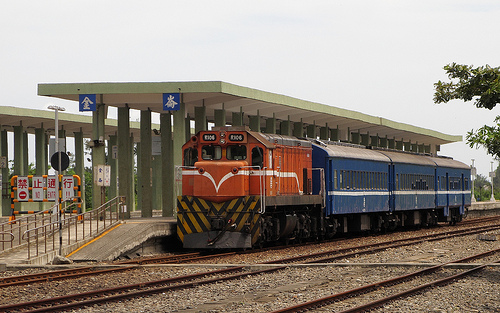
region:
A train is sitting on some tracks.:
[172, 125, 473, 256]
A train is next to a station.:
[175, 125, 473, 252]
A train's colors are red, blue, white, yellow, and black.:
[173, 127, 470, 250]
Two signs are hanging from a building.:
[75, 88, 185, 113]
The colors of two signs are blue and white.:
[77, 90, 179, 111]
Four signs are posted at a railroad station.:
[16, 173, 74, 201]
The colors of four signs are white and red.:
[16, 175, 74, 201]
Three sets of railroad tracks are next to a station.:
[0, 204, 498, 311]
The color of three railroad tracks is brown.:
[0, 210, 498, 312]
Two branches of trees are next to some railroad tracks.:
[430, 61, 498, 205]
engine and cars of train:
[164, 123, 480, 256]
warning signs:
[10, 171, 95, 222]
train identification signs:
[67, 90, 185, 117]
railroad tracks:
[2, 206, 496, 311]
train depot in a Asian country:
[30, 76, 484, 248]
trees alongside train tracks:
[409, 43, 494, 272]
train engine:
[164, 124, 320, 261]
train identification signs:
[195, 125, 250, 143]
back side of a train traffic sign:
[45, 145, 86, 270]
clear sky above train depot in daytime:
[0, 208, 498, 218]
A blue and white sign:
[156, 86, 186, 119]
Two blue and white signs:
[76, 89, 186, 116]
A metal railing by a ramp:
[25, 216, 72, 266]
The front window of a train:
[197, 141, 249, 163]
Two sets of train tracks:
[138, 252, 441, 311]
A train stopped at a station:
[167, 120, 476, 256]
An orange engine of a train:
[170, 122, 325, 255]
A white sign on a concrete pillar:
[90, 161, 117, 194]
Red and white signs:
[10, 170, 82, 209]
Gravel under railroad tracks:
[159, 255, 461, 293]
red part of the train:
[175, 125, 317, 200]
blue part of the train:
[306, 138, 476, 216]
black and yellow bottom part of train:
[171, 193, 265, 250]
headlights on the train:
[196, 163, 241, 175]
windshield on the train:
[197, 142, 250, 166]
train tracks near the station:
[1, 211, 498, 311]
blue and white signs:
[78, 93, 181, 117]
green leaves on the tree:
[431, 60, 498, 159]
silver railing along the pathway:
[0, 190, 130, 258]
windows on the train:
[335, 168, 472, 191]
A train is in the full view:
[163, 109, 480, 254]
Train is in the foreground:
[165, 113, 480, 257]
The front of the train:
[171, 123, 284, 253]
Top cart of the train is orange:
[177, 121, 317, 258]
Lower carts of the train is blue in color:
[313, 120, 482, 235]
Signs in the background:
[13, 165, 78, 210]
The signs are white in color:
[7, 170, 82, 221]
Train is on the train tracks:
[167, 119, 482, 308]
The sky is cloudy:
[1, 0, 498, 167]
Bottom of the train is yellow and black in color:
[171, 195, 261, 246]